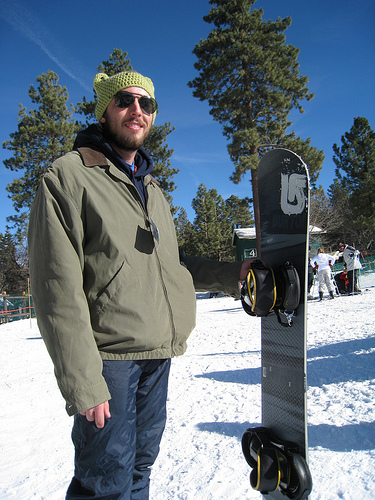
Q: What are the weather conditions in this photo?
A: It is clear.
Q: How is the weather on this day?
A: It is clear.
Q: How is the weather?
A: It is clear.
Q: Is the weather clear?
A: Yes, it is clear.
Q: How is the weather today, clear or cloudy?
A: It is clear.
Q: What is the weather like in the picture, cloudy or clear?
A: It is clear.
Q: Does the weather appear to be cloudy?
A: No, it is clear.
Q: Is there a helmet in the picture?
A: No, there are no helmets.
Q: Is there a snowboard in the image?
A: Yes, there is a snowboard.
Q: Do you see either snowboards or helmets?
A: Yes, there is a snowboard.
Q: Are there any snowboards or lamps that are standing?
A: Yes, the snowboard is standing.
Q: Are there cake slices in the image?
A: No, there are no cake slices.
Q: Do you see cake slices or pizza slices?
A: No, there are no cake slices or pizza slices.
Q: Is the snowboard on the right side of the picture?
A: Yes, the snowboard is on the right of the image.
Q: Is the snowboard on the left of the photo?
A: No, the snowboard is on the right of the image.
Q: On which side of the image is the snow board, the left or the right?
A: The snow board is on the right of the image.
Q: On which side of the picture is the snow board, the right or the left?
A: The snow board is on the right of the image.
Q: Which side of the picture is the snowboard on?
A: The snowboard is on the right of the image.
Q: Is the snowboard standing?
A: Yes, the snowboard is standing.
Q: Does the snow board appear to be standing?
A: Yes, the snow board is standing.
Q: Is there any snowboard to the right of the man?
A: Yes, there is a snowboard to the right of the man.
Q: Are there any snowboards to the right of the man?
A: Yes, there is a snowboard to the right of the man.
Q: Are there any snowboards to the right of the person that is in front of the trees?
A: Yes, there is a snowboard to the right of the man.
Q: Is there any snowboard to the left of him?
A: No, the snowboard is to the right of the man.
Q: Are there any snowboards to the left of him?
A: No, the snowboard is to the right of the man.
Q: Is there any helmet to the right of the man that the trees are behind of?
A: No, there is a snowboard to the right of the man.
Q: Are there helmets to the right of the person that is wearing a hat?
A: No, there is a snowboard to the right of the man.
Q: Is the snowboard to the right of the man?
A: Yes, the snowboard is to the right of the man.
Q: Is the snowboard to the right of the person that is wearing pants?
A: Yes, the snowboard is to the right of the man.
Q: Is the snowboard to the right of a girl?
A: No, the snowboard is to the right of the man.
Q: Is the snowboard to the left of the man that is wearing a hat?
A: No, the snowboard is to the right of the man.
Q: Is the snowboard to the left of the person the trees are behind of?
A: No, the snowboard is to the right of the man.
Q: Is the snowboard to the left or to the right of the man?
A: The snowboard is to the right of the man.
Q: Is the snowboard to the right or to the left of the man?
A: The snowboard is to the right of the man.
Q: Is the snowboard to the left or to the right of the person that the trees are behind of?
A: The snowboard is to the right of the man.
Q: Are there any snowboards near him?
A: Yes, there is a snowboard near the man.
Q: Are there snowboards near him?
A: Yes, there is a snowboard near the man.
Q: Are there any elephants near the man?
A: No, there is a snowboard near the man.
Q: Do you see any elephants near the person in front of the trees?
A: No, there is a snowboard near the man.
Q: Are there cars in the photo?
A: No, there are no cars.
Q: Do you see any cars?
A: No, there are no cars.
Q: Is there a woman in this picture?
A: No, there are no women.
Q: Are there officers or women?
A: No, there are no women or officers.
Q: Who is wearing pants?
A: The man is wearing pants.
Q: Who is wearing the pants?
A: The man is wearing pants.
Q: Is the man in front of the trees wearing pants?
A: Yes, the man is wearing pants.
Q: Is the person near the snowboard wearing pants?
A: Yes, the man is wearing pants.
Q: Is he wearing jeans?
A: No, the man is wearing pants.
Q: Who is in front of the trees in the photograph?
A: The man is in front of the trees.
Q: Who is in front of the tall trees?
A: The man is in front of the trees.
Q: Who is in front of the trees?
A: The man is in front of the trees.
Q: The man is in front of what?
A: The man is in front of the trees.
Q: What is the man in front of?
A: The man is in front of the trees.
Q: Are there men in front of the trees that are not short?
A: Yes, there is a man in front of the trees.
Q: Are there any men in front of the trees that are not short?
A: Yes, there is a man in front of the trees.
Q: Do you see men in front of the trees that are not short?
A: Yes, there is a man in front of the trees.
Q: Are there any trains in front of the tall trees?
A: No, there is a man in front of the trees.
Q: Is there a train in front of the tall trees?
A: No, there is a man in front of the trees.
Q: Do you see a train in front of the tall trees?
A: No, there is a man in front of the trees.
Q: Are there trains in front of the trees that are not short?
A: No, there is a man in front of the trees.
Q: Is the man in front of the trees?
A: Yes, the man is in front of the trees.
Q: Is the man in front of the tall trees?
A: Yes, the man is in front of the trees.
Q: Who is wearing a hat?
A: The man is wearing a hat.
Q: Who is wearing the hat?
A: The man is wearing a hat.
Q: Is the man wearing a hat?
A: Yes, the man is wearing a hat.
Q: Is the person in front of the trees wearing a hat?
A: Yes, the man is wearing a hat.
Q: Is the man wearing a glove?
A: No, the man is wearing a hat.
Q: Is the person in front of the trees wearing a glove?
A: No, the man is wearing a hat.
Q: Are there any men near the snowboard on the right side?
A: Yes, there is a man near the snowboard.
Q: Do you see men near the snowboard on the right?
A: Yes, there is a man near the snowboard.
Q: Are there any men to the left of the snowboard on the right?
A: Yes, there is a man to the left of the snowboard.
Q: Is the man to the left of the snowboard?
A: Yes, the man is to the left of the snowboard.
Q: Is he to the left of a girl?
A: No, the man is to the left of the snowboard.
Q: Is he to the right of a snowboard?
A: No, the man is to the left of a snowboard.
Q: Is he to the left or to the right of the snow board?
A: The man is to the left of the snow board.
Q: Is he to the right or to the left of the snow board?
A: The man is to the left of the snow board.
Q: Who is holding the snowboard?
A: The man is holding the snowboard.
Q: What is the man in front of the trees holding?
A: The man is holding the snowboard.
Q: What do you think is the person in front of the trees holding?
A: The man is holding the snowboard.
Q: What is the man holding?
A: The man is holding the snowboard.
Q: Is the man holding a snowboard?
A: Yes, the man is holding a snowboard.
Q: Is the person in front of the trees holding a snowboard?
A: Yes, the man is holding a snowboard.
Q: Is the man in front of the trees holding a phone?
A: No, the man is holding a snowboard.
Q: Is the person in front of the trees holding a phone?
A: No, the man is holding a snowboard.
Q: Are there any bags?
A: No, there are no bags.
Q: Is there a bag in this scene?
A: No, there are no bags.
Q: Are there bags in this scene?
A: No, there are no bags.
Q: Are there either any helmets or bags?
A: No, there are no bags or helmets.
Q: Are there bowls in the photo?
A: No, there are no bowls.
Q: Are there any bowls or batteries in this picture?
A: No, there are no bowls or batteries.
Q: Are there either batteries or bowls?
A: No, there are no bowls or batteries.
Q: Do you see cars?
A: No, there are no cars.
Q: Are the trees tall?
A: Yes, the trees are tall.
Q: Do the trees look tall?
A: Yes, the trees are tall.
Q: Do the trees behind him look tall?
A: Yes, the trees are tall.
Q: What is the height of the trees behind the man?
A: The trees are tall.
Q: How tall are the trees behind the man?
A: The trees are tall.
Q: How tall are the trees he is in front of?
A: The trees are tall.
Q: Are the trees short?
A: No, the trees are tall.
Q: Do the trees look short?
A: No, the trees are tall.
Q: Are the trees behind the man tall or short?
A: The trees are tall.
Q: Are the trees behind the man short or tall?
A: The trees are tall.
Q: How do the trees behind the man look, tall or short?
A: The trees are tall.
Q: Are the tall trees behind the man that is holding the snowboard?
A: Yes, the trees are behind the man.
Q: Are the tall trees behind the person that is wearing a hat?
A: Yes, the trees are behind the man.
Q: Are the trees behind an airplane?
A: No, the trees are behind the man.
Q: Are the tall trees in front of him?
A: No, the trees are behind the man.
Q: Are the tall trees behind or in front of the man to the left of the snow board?
A: The trees are behind the man.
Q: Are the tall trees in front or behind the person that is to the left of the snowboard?
A: The trees are behind the man.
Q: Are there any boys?
A: No, there are no boys.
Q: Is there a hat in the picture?
A: Yes, there is a hat.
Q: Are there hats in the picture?
A: Yes, there is a hat.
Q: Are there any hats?
A: Yes, there is a hat.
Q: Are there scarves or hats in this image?
A: Yes, there is a hat.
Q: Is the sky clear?
A: Yes, the sky is clear.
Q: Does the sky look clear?
A: Yes, the sky is clear.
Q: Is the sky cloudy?
A: No, the sky is clear.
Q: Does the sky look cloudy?
A: No, the sky is clear.